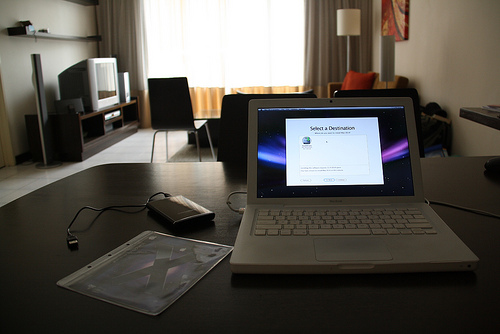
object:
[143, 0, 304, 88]
window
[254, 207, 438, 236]
keyboard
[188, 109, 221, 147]
table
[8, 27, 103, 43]
shelf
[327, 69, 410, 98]
loveseat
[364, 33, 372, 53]
shade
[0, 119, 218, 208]
floor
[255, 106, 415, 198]
screen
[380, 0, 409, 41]
painting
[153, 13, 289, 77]
light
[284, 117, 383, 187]
window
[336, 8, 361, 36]
lamp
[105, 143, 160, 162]
ground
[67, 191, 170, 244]
cord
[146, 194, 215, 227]
hard drive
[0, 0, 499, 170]
wall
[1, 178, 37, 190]
tile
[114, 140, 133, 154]
tile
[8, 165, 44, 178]
tile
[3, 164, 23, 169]
tile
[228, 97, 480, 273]
computer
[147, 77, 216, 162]
chair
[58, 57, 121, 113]
television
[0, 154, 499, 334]
desk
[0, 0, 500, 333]
room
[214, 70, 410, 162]
furniture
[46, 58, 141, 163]
entertainment center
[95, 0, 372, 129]
curtains